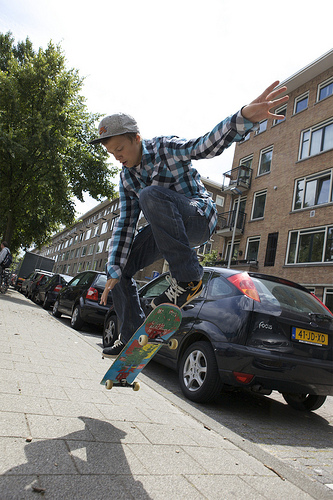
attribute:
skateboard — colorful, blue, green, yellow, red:
[98, 298, 184, 393]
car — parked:
[129, 254, 331, 414]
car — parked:
[55, 269, 158, 344]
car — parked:
[34, 274, 76, 314]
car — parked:
[18, 269, 54, 296]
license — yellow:
[293, 331, 328, 350]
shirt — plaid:
[94, 112, 254, 282]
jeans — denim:
[100, 189, 212, 344]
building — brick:
[225, 52, 330, 407]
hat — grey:
[92, 112, 135, 144]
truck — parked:
[13, 245, 59, 300]